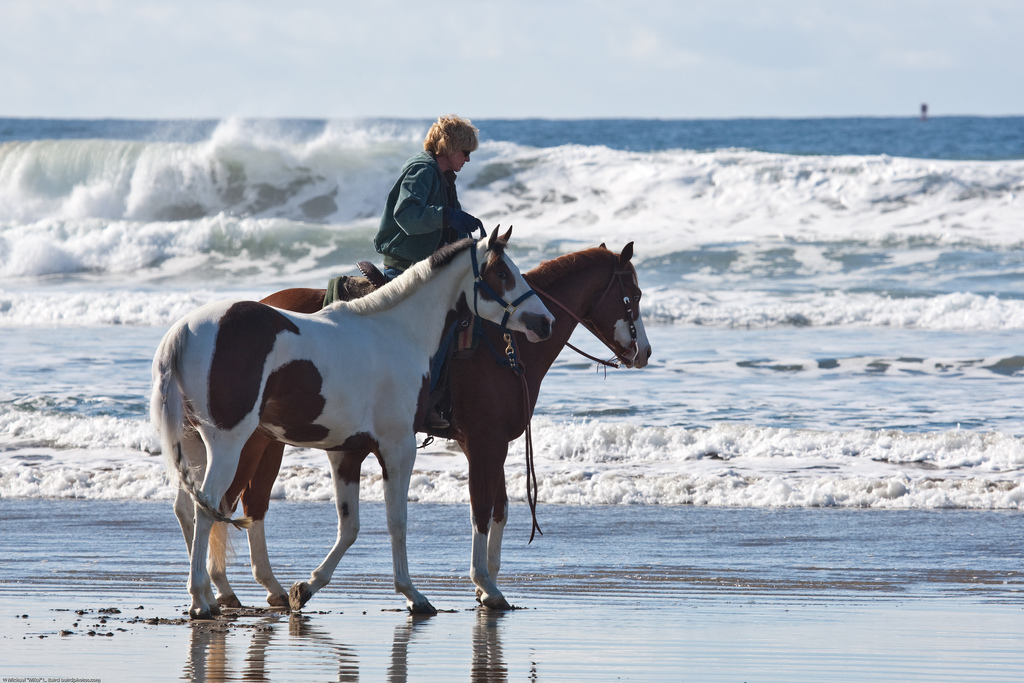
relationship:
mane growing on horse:
[335, 232, 480, 317] [153, 224, 562, 622]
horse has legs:
[153, 224, 562, 622] [188, 414, 245, 615]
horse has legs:
[211, 237, 652, 609] [211, 434, 294, 616]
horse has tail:
[153, 224, 562, 622] [147, 322, 256, 537]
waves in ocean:
[4, 118, 897, 259] [2, 112, 1007, 527]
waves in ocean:
[0, 118, 1022, 277] [2, 112, 1007, 527]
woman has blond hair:
[371, 106, 484, 275] [418, 109, 483, 164]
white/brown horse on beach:
[141, 219, 561, 611] [3, 422, 991, 678]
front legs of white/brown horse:
[293, 443, 438, 612] [141, 219, 561, 611]